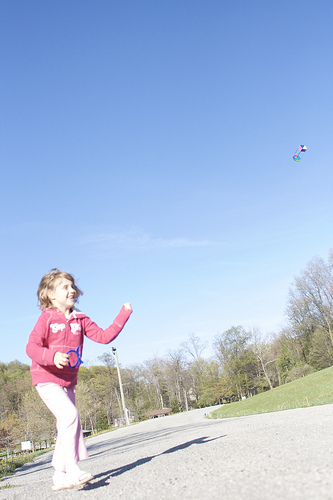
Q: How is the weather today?
A: It is clear.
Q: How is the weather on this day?
A: It is clear.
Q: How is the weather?
A: It is clear.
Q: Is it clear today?
A: Yes, it is clear.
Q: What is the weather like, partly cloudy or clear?
A: It is clear.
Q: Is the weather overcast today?
A: No, it is clear.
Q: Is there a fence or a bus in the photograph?
A: No, there are no fences or buses.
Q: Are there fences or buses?
A: No, there are no fences or buses.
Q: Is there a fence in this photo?
A: No, there are no fences.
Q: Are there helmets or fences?
A: No, there are no fences or helmets.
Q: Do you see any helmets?
A: No, there are no helmets.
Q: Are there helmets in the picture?
A: No, there are no helmets.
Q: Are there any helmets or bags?
A: No, there are no helmets or bags.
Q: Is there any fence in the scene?
A: No, there are no fences.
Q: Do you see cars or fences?
A: No, there are no fences or cars.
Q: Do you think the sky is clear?
A: Yes, the sky is clear.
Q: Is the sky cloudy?
A: No, the sky is clear.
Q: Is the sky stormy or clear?
A: The sky is clear.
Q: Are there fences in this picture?
A: No, there are no fences.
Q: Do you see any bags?
A: No, there are no bags.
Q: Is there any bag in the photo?
A: No, there are no bags.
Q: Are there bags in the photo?
A: No, there are no bags.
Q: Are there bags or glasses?
A: No, there are no bags or glasses.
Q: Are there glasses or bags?
A: No, there are no bags or glasses.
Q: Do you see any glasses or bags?
A: No, there are no bags or glasses.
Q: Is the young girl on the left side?
A: Yes, the girl is on the left of the image.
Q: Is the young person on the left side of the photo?
A: Yes, the girl is on the left of the image.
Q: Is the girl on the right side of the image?
A: No, the girl is on the left of the image.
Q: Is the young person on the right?
A: No, the girl is on the left of the image.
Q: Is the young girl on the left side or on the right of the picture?
A: The girl is on the left of the image.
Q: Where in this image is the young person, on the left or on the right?
A: The girl is on the left of the image.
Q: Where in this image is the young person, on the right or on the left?
A: The girl is on the left of the image.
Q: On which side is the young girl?
A: The girl is on the left of the image.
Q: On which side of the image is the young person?
A: The girl is on the left of the image.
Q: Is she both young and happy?
A: Yes, the girl is young and happy.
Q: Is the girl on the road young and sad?
A: No, the girl is young but happy.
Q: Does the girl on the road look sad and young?
A: No, the girl is young but happy.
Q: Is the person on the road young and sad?
A: No, the girl is young but happy.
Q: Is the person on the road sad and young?
A: No, the girl is young but happy.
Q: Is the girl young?
A: Yes, the girl is young.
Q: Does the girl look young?
A: Yes, the girl is young.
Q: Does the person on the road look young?
A: Yes, the girl is young.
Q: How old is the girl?
A: The girl is young.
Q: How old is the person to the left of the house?
A: The girl is young.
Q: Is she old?
A: No, the girl is young.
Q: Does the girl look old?
A: No, the girl is young.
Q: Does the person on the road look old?
A: No, the girl is young.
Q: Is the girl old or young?
A: The girl is young.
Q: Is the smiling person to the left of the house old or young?
A: The girl is young.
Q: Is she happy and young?
A: Yes, the girl is happy and young.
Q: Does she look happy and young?
A: Yes, the girl is happy and young.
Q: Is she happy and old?
A: No, the girl is happy but young.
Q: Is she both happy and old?
A: No, the girl is happy but young.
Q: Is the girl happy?
A: Yes, the girl is happy.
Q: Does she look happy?
A: Yes, the girl is happy.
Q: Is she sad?
A: No, the girl is happy.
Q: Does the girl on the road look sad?
A: No, the girl is happy.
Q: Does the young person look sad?
A: No, the girl is happy.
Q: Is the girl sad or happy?
A: The girl is happy.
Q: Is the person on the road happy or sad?
A: The girl is happy.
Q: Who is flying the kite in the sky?
A: The girl is flying the kite.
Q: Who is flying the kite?
A: The girl is flying the kite.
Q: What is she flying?
A: The girl is flying the kite.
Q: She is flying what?
A: The girl is flying the kite.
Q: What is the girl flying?
A: The girl is flying the kite.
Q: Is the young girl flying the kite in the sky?
A: Yes, the girl is flying the kite.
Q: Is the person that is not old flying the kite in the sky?
A: Yes, the girl is flying the kite.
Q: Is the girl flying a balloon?
A: No, the girl is flying the kite.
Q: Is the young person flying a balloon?
A: No, the girl is flying the kite.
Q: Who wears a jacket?
A: The girl wears a jacket.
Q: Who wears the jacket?
A: The girl wears a jacket.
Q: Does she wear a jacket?
A: Yes, the girl wears a jacket.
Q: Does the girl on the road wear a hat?
A: No, the girl wears a jacket.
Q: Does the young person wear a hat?
A: No, the girl wears a jacket.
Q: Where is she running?
A: The girl is running on the road.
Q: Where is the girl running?
A: The girl is running on the road.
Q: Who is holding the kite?
A: The girl is holding the kite.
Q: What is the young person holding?
A: The girl is holding the kite.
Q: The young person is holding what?
A: The girl is holding the kite.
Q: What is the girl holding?
A: The girl is holding the kite.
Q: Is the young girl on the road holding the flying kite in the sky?
A: Yes, the girl is holding the kite.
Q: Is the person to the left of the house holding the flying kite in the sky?
A: Yes, the girl is holding the kite.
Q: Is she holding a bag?
A: No, the girl is holding the kite.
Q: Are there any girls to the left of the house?
A: Yes, there is a girl to the left of the house.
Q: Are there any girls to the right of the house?
A: No, the girl is to the left of the house.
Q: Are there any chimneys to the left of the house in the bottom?
A: No, there is a girl to the left of the house.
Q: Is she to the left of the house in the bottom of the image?
A: Yes, the girl is to the left of the house.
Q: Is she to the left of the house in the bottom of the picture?
A: Yes, the girl is to the left of the house.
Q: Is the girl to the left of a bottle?
A: No, the girl is to the left of the house.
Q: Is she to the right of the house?
A: No, the girl is to the left of the house.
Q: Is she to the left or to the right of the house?
A: The girl is to the left of the house.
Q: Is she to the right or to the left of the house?
A: The girl is to the left of the house.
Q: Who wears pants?
A: The girl wears pants.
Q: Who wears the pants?
A: The girl wears pants.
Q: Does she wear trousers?
A: Yes, the girl wears trousers.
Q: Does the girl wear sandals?
A: No, the girl wears trousers.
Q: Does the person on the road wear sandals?
A: No, the girl wears trousers.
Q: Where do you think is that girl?
A: The girl is on the road.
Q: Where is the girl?
A: The girl is on the road.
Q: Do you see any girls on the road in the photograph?
A: Yes, there is a girl on the road.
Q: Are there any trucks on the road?
A: No, there is a girl on the road.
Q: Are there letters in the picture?
A: Yes, there are letters.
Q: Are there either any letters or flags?
A: Yes, there are letters.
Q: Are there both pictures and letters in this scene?
A: No, there are letters but no pictures.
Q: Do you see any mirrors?
A: No, there are no mirrors.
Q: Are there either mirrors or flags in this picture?
A: No, there are no mirrors or flags.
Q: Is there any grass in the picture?
A: Yes, there is grass.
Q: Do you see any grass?
A: Yes, there is grass.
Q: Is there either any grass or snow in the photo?
A: Yes, there is grass.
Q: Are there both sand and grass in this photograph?
A: No, there is grass but no sand.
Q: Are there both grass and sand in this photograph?
A: No, there is grass but no sand.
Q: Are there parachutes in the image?
A: No, there are no parachutes.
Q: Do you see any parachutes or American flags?
A: No, there are no parachutes or American flags.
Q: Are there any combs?
A: No, there are no combs.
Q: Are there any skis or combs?
A: No, there are no combs or skis.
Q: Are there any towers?
A: No, there are no towers.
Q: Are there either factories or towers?
A: No, there are no towers or factories.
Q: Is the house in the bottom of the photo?
A: Yes, the house is in the bottom of the image.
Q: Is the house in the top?
A: No, the house is in the bottom of the image.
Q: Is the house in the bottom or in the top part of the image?
A: The house is in the bottom of the image.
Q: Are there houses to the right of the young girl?
A: Yes, there is a house to the right of the girl.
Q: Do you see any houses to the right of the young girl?
A: Yes, there is a house to the right of the girl.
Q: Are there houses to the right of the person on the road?
A: Yes, there is a house to the right of the girl.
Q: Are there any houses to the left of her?
A: No, the house is to the right of the girl.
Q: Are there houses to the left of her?
A: No, the house is to the right of the girl.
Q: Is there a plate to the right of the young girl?
A: No, there is a house to the right of the girl.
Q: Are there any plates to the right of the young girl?
A: No, there is a house to the right of the girl.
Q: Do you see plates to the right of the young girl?
A: No, there is a house to the right of the girl.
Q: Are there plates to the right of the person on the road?
A: No, there is a house to the right of the girl.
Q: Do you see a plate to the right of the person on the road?
A: No, there is a house to the right of the girl.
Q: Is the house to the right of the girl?
A: Yes, the house is to the right of the girl.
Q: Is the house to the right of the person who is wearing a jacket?
A: Yes, the house is to the right of the girl.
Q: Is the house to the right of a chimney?
A: No, the house is to the right of the girl.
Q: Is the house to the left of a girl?
A: No, the house is to the right of a girl.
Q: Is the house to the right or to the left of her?
A: The house is to the right of the girl.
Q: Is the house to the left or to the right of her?
A: The house is to the right of the girl.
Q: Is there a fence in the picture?
A: No, there are no fences.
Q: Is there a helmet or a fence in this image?
A: No, there are no fences or helmets.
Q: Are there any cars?
A: No, there are no cars.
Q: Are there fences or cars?
A: No, there are no cars or fences.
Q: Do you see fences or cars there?
A: No, there are no cars or fences.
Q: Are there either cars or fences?
A: No, there are no cars or fences.